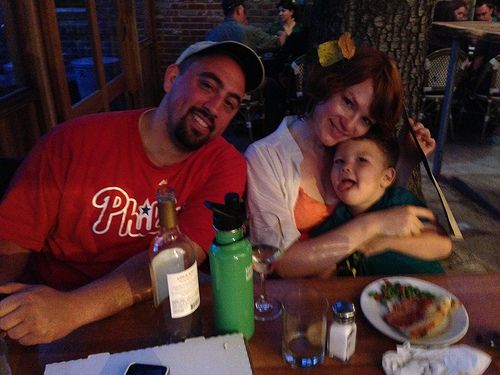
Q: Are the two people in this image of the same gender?
A: No, they are both male and female.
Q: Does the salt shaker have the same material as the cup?
A: Yes, both the salt shaker and the cup are made of glass.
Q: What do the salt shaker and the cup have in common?
A: The material, both the salt shaker and the cup are glass.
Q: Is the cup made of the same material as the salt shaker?
A: Yes, both the cup and the salt shaker are made of glass.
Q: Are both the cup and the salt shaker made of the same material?
A: Yes, both the cup and the salt shaker are made of glass.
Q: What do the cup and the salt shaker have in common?
A: The material, both the cup and the salt shaker are glass.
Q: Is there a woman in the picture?
A: Yes, there is a woman.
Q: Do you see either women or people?
A: Yes, there is a woman.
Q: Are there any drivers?
A: No, there are no drivers.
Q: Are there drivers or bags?
A: No, there are no drivers or bags.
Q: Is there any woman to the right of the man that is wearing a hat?
A: Yes, there is a woman to the right of the man.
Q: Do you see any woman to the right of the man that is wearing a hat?
A: Yes, there is a woman to the right of the man.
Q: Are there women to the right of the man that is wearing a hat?
A: Yes, there is a woman to the right of the man.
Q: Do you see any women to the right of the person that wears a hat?
A: Yes, there is a woman to the right of the man.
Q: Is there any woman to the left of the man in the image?
A: No, the woman is to the right of the man.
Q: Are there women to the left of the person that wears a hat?
A: No, the woman is to the right of the man.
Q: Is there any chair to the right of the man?
A: No, there is a woman to the right of the man.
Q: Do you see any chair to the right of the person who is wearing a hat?
A: No, there is a woman to the right of the man.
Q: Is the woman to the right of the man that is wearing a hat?
A: Yes, the woman is to the right of the man.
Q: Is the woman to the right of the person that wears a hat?
A: Yes, the woman is to the right of the man.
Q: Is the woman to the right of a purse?
A: No, the woman is to the right of the man.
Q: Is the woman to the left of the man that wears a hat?
A: No, the woman is to the right of the man.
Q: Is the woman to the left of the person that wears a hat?
A: No, the woman is to the right of the man.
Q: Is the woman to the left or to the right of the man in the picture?
A: The woman is to the right of the man.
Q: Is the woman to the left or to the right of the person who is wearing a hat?
A: The woman is to the right of the man.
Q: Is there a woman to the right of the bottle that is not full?
A: Yes, there is a woman to the right of the bottle.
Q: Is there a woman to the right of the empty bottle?
A: Yes, there is a woman to the right of the bottle.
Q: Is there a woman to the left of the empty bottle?
A: No, the woman is to the right of the bottle.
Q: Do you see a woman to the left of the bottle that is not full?
A: No, the woman is to the right of the bottle.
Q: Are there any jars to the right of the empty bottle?
A: No, there is a woman to the right of the bottle.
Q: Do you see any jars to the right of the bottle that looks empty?
A: No, there is a woman to the right of the bottle.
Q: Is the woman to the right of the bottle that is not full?
A: Yes, the woman is to the right of the bottle.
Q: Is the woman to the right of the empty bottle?
A: Yes, the woman is to the right of the bottle.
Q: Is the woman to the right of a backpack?
A: No, the woman is to the right of the bottle.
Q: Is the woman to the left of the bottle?
A: No, the woman is to the right of the bottle.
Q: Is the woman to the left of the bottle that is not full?
A: No, the woman is to the right of the bottle.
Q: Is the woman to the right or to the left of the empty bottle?
A: The woman is to the right of the bottle.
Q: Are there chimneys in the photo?
A: No, there are no chimneys.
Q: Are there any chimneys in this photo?
A: No, there are no chimneys.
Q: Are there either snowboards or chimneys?
A: No, there are no chimneys or snowboards.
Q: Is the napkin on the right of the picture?
A: Yes, the napkin is on the right of the image.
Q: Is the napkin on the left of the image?
A: No, the napkin is on the right of the image.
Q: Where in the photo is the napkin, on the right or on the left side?
A: The napkin is on the right of the image.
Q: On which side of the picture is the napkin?
A: The napkin is on the right of the image.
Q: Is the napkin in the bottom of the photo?
A: Yes, the napkin is in the bottom of the image.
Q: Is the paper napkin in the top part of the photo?
A: No, the napkin is in the bottom of the image.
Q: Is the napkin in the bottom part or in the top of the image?
A: The napkin is in the bottom of the image.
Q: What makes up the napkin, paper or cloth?
A: The napkin is made of paper.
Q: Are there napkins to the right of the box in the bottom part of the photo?
A: Yes, there is a napkin to the right of the box.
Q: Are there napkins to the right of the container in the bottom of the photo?
A: Yes, there is a napkin to the right of the box.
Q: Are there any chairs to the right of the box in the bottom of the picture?
A: No, there is a napkin to the right of the box.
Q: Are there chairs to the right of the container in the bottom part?
A: No, there is a napkin to the right of the box.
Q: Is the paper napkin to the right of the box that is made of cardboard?
A: Yes, the napkin is to the right of the box.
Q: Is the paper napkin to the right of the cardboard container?
A: Yes, the napkin is to the right of the box.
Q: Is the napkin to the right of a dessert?
A: No, the napkin is to the right of the box.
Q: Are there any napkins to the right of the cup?
A: Yes, there is a napkin to the right of the cup.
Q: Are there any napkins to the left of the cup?
A: No, the napkin is to the right of the cup.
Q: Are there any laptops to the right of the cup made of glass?
A: No, there is a napkin to the right of the cup.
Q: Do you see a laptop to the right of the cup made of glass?
A: No, there is a napkin to the right of the cup.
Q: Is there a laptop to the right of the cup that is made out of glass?
A: No, there is a napkin to the right of the cup.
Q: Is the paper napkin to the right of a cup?
A: Yes, the napkin is to the right of a cup.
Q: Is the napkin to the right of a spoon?
A: No, the napkin is to the right of a cup.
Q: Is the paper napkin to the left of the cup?
A: No, the napkin is to the right of the cup.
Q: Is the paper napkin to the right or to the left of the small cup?
A: The napkin is to the right of the cup.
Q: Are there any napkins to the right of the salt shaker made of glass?
A: Yes, there is a napkin to the right of the salt shaker.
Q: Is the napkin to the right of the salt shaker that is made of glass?
A: Yes, the napkin is to the right of the salt shaker.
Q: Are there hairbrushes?
A: No, there are no hairbrushes.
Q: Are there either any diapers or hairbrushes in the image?
A: No, there are no hairbrushes or diapers.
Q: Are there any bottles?
A: Yes, there is a bottle.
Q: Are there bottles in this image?
A: Yes, there is a bottle.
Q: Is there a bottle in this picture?
A: Yes, there is a bottle.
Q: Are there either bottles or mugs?
A: Yes, there is a bottle.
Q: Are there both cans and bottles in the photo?
A: No, there is a bottle but no cans.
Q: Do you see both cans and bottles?
A: No, there is a bottle but no cans.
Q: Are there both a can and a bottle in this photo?
A: No, there is a bottle but no cans.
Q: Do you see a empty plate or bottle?
A: Yes, there is an empty bottle.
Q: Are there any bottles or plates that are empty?
A: Yes, the bottle is empty.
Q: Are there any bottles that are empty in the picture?
A: Yes, there is an empty bottle.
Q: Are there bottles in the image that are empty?
A: Yes, there is a bottle that is empty.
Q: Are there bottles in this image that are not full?
A: Yes, there is a empty bottle.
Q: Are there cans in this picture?
A: No, there are no cans.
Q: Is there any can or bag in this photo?
A: No, there are no cans or bags.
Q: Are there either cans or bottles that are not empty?
A: No, there is a bottle but it is empty.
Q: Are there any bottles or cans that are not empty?
A: No, there is a bottle but it is empty.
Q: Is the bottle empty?
A: Yes, the bottle is empty.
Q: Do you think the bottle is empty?
A: Yes, the bottle is empty.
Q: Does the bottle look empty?
A: Yes, the bottle is empty.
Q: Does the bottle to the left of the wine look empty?
A: Yes, the bottle is empty.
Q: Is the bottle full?
A: No, the bottle is empty.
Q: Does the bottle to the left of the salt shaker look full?
A: No, the bottle is empty.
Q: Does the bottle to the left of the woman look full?
A: No, the bottle is empty.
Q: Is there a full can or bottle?
A: No, there is a bottle but it is empty.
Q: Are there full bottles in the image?
A: No, there is a bottle but it is empty.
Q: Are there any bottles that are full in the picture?
A: No, there is a bottle but it is empty.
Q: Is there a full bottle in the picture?
A: No, there is a bottle but it is empty.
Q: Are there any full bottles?
A: No, there is a bottle but it is empty.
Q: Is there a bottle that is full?
A: No, there is a bottle but it is empty.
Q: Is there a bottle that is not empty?
A: No, there is a bottle but it is empty.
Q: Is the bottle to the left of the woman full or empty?
A: The bottle is empty.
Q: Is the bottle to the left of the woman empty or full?
A: The bottle is empty.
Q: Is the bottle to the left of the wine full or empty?
A: The bottle is empty.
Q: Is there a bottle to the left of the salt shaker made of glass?
A: Yes, there is a bottle to the left of the salt shaker.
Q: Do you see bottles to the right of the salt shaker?
A: No, the bottle is to the left of the salt shaker.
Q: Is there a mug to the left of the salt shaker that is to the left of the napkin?
A: No, there is a bottle to the left of the salt shaker.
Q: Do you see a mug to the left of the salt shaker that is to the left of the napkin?
A: No, there is a bottle to the left of the salt shaker.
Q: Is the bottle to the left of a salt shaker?
A: Yes, the bottle is to the left of a salt shaker.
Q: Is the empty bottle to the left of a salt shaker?
A: Yes, the bottle is to the left of a salt shaker.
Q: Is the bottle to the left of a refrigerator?
A: No, the bottle is to the left of a salt shaker.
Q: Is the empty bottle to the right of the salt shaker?
A: No, the bottle is to the left of the salt shaker.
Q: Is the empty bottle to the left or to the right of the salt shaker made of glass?
A: The bottle is to the left of the salt shaker.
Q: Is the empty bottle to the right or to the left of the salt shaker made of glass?
A: The bottle is to the left of the salt shaker.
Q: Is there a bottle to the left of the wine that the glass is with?
A: Yes, there is a bottle to the left of the wine.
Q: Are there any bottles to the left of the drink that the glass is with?
A: Yes, there is a bottle to the left of the wine.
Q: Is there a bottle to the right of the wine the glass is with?
A: No, the bottle is to the left of the wine.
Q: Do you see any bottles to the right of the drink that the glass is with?
A: No, the bottle is to the left of the wine.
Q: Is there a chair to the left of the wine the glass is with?
A: No, there is a bottle to the left of the wine.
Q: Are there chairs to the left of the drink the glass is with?
A: No, there is a bottle to the left of the wine.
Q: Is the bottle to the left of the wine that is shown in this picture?
A: Yes, the bottle is to the left of the wine.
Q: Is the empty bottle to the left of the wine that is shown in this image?
A: Yes, the bottle is to the left of the wine.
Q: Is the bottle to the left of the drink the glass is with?
A: Yes, the bottle is to the left of the wine.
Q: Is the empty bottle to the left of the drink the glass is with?
A: Yes, the bottle is to the left of the wine.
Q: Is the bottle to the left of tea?
A: No, the bottle is to the left of the wine.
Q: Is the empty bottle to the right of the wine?
A: No, the bottle is to the left of the wine.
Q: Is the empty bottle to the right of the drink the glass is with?
A: No, the bottle is to the left of the wine.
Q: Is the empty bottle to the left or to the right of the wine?
A: The bottle is to the left of the wine.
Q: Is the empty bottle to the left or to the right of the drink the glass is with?
A: The bottle is to the left of the wine.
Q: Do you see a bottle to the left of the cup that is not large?
A: Yes, there is a bottle to the left of the cup.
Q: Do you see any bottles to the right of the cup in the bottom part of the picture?
A: No, the bottle is to the left of the cup.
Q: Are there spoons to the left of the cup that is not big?
A: No, there is a bottle to the left of the cup.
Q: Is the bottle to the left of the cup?
A: Yes, the bottle is to the left of the cup.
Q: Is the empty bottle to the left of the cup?
A: Yes, the bottle is to the left of the cup.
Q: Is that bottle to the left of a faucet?
A: No, the bottle is to the left of the cup.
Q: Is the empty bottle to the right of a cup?
A: No, the bottle is to the left of a cup.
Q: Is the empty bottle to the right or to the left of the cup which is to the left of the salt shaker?
A: The bottle is to the left of the cup.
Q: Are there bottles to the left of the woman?
A: Yes, there is a bottle to the left of the woman.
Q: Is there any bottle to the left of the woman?
A: Yes, there is a bottle to the left of the woman.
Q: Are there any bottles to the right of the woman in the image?
A: No, the bottle is to the left of the woman.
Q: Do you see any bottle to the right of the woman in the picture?
A: No, the bottle is to the left of the woman.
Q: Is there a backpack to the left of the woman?
A: No, there is a bottle to the left of the woman.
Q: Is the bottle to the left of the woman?
A: Yes, the bottle is to the left of the woman.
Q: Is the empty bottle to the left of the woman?
A: Yes, the bottle is to the left of the woman.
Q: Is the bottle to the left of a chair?
A: No, the bottle is to the left of the woman.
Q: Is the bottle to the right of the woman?
A: No, the bottle is to the left of the woman.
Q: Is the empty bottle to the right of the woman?
A: No, the bottle is to the left of the woman.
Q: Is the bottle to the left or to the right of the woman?
A: The bottle is to the left of the woman.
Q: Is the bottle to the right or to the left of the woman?
A: The bottle is to the left of the woman.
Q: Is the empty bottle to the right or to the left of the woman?
A: The bottle is to the left of the woman.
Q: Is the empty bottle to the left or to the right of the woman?
A: The bottle is to the left of the woman.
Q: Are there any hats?
A: Yes, there is a hat.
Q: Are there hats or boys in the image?
A: Yes, there is a hat.